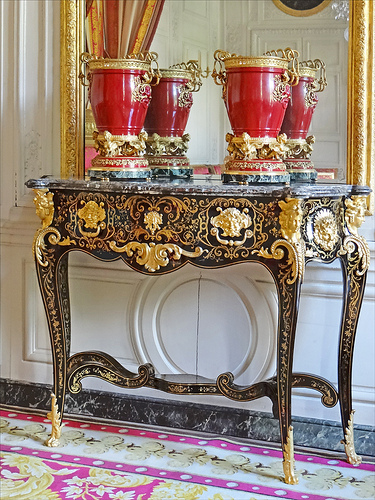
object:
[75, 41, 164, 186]
vase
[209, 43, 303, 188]
vase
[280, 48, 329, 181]
vase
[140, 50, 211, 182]
vase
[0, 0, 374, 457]
wall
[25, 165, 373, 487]
table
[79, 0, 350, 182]
mirror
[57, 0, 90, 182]
frame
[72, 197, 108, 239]
sculpture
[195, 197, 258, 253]
details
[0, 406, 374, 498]
rug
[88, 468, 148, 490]
designs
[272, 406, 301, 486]
leg